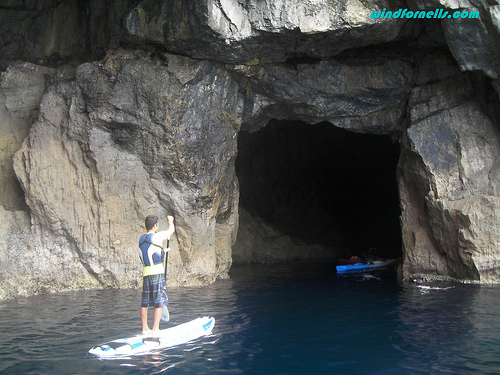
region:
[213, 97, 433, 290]
A cave opening.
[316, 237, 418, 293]
A boat in the cave.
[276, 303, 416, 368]
The water is deep blue.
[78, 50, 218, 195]
The stone is rough.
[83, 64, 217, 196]
The stone is gray, black and brown.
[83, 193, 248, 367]
A person paddling.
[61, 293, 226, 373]
Their board is white.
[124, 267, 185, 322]
The person is wearing shorts.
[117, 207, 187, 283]
The person is wearing a yellow shirt.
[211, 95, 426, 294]
The opening is large.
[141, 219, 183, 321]
this is a man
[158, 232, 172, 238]
the man is light skinned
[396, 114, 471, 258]
this is a rock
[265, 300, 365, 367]
this is a water body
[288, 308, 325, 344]
the water is calm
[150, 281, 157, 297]
this is a short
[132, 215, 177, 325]
the man is standing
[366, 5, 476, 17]
this is a writing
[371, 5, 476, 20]
the writing is in blue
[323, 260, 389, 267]
this is a boat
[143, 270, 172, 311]
man in blue plaid shorts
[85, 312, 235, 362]
white and blue canoe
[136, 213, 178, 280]
wan in dark blue life vest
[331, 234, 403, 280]
canoe entering stone tunnel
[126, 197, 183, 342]
outstretched right arm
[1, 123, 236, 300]
sunlight reflected on stone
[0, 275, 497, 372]
stones and tunnel reflected in water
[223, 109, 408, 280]
dark stone tunnel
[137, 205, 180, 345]
man with short brown hair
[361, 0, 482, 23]
photo belongs to windfornells.com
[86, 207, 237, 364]
a man on a kayak going towards a cave.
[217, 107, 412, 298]
a cave in the side of a rock.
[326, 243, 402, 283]
a paddle boarder going into a cave.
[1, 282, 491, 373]
a beautiful pool of water.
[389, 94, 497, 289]
a large rock near a cave.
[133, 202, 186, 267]
a man in a life jacket.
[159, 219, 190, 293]
a man holding a paddle.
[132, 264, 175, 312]
a man in blue shorts.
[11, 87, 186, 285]
a large rock.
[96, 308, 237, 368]
a board on water.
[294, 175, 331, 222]
part of a hollow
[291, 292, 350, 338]
part of a water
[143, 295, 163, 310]
edge of a short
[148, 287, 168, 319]
part of a short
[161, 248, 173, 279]
part of a handle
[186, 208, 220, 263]
edge of a cave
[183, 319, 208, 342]
edge of a boat